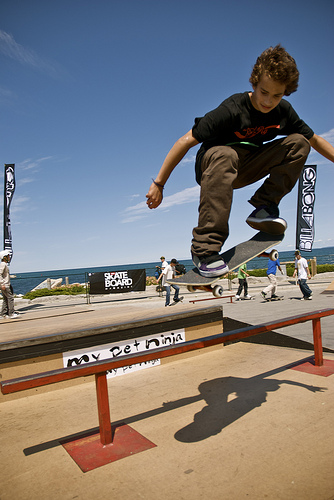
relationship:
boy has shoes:
[145, 46, 334, 279] [190, 208, 286, 277]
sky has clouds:
[1, 1, 333, 251] [121, 186, 198, 221]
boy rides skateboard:
[145, 46, 334, 279] [166, 228, 286, 296]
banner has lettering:
[87, 267, 145, 295] [104, 271, 132, 290]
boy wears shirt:
[154, 256, 182, 307] [161, 265, 175, 288]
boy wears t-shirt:
[291, 247, 314, 300] [292, 258, 307, 281]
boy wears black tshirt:
[145, 46, 334, 279] [190, 90, 315, 184]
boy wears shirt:
[235, 264, 250, 296] [238, 265, 245, 278]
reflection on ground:
[173, 374, 327, 443] [1, 270, 333, 498]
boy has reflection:
[145, 46, 334, 279] [173, 374, 327, 443]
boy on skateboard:
[121, 22, 317, 253] [166, 228, 286, 296]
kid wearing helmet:
[0, 244, 17, 326] [0, 247, 14, 262]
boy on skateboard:
[145, 46, 334, 279] [166, 228, 286, 296]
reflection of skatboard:
[173, 374, 327, 443] [165, 230, 284, 297]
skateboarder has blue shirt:
[263, 255, 283, 300] [268, 259, 278, 274]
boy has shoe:
[145, 46, 334, 279] [189, 256, 230, 279]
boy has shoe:
[145, 46, 334, 279] [244, 207, 285, 231]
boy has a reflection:
[145, 46, 334, 279] [173, 374, 326, 443]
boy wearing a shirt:
[292, 249, 314, 300] [159, 262, 174, 287]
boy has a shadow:
[145, 46, 334, 279] [156, 369, 332, 443]